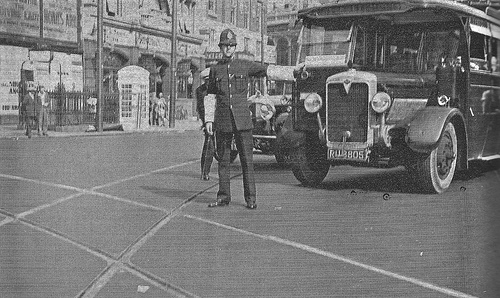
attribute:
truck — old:
[279, 18, 493, 196]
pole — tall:
[74, 7, 134, 103]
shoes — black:
[209, 184, 292, 226]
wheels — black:
[254, 127, 479, 192]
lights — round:
[293, 87, 423, 108]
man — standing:
[155, 3, 283, 199]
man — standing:
[167, 2, 279, 200]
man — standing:
[207, 64, 253, 227]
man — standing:
[207, 76, 271, 190]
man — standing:
[195, 94, 256, 213]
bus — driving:
[264, 17, 444, 157]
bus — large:
[272, 10, 471, 192]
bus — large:
[303, 27, 482, 190]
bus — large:
[325, 3, 452, 169]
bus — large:
[312, 47, 456, 177]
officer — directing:
[211, 35, 279, 279]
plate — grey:
[329, 138, 384, 170]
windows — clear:
[320, 11, 474, 60]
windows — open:
[456, 29, 489, 97]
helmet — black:
[211, 22, 246, 49]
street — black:
[49, 187, 388, 275]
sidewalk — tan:
[36, 116, 206, 139]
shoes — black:
[211, 185, 311, 235]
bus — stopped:
[318, 39, 436, 154]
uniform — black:
[216, 54, 261, 143]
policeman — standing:
[158, 6, 267, 190]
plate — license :
[325, 144, 375, 164]